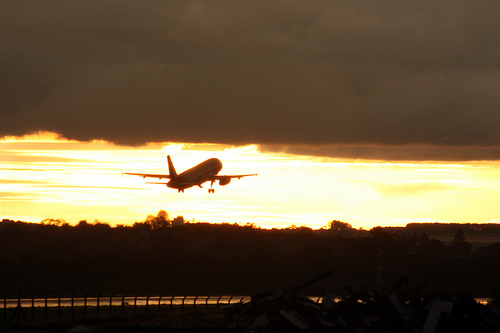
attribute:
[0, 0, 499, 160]
clouds — dark, grey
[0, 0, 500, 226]
sky — sunlit, yellow, golden, cloudy, sunlight, white, blue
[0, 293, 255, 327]
fence — long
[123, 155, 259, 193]
plane — brown, flying, taking off, dark, large, black, traveling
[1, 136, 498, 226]
horizon — bright, sunny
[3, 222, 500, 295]
shrubbery — thick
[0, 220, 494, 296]
trees — dark, growing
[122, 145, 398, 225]
sun — rising, bright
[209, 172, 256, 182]
wing — long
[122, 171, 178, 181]
wing — long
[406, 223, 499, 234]
train — passing